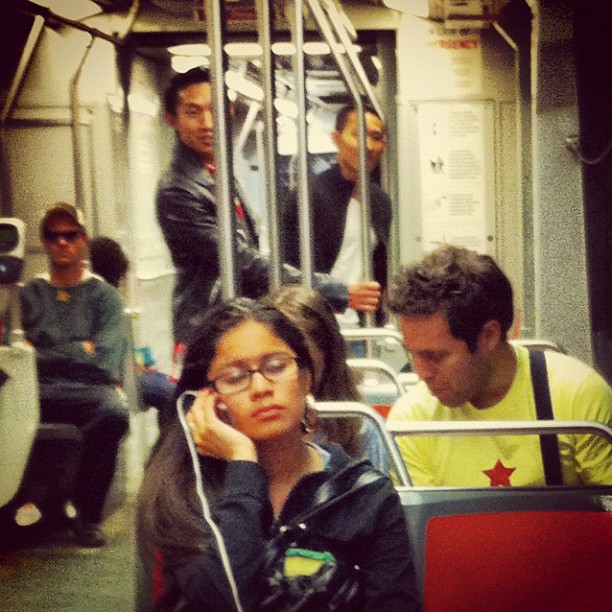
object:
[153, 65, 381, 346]
man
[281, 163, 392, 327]
coat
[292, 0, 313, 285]
pole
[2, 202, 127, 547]
man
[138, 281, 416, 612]
twopeople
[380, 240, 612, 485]
man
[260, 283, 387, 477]
person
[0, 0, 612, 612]
subway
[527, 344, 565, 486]
bag